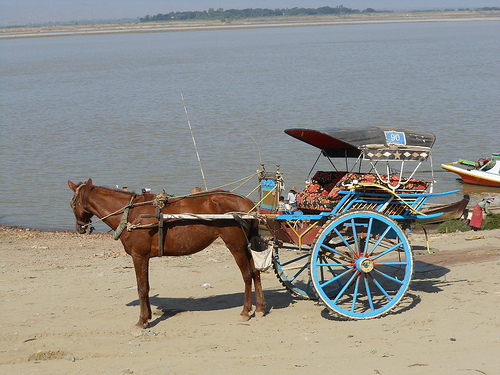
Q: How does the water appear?
A: Calm.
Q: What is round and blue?
A: Wheel.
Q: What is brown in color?
A: Horse.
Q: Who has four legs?
A: The horse.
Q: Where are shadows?
A: On the dirt.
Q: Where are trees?
A: In the far distance.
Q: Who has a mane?
A: A horse.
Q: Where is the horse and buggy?
A: Near the water.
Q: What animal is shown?
A: Horse.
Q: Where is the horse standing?
A: On the sand.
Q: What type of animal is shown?
A: Horse.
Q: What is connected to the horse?
A: Buggy.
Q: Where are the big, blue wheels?
A: On a wagon, hitched to a horse.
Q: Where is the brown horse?
A: Standing in front of a wagon with blue wheels.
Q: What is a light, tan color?
A: The sand on the beach.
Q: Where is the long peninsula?
A: In the distance, between two sections of water.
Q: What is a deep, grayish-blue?
A: The water.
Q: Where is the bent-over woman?
A: Near a brown, docked boat and some green shrubs.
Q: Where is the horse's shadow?
A: Right below the horse.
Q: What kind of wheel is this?
A: A large blue wheel.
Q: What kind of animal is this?
A: A brown horse.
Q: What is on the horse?
A: A harness.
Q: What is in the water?
A: A boat.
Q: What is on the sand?
A: A buggy.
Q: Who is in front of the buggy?
A: A horse.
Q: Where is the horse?
A: The beach.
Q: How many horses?
A: 1.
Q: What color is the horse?
A: Brown.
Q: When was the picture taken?
A: Daytime.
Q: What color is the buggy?
A: Blue.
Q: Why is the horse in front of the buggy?
A: To lead it.